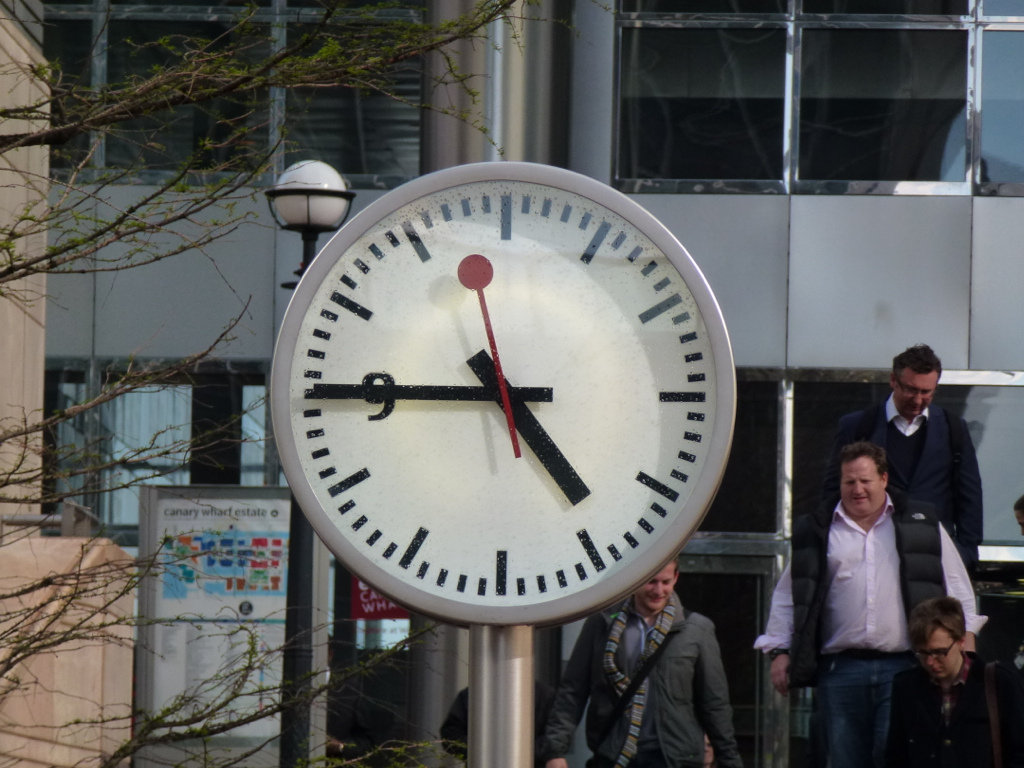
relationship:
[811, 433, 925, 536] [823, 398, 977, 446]
head above shoulders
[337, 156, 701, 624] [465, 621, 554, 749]
clock attached to pole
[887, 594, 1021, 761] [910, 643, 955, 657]
person wearing glasses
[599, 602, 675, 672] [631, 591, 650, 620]
scarf around neck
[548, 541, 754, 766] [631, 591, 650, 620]
man has neck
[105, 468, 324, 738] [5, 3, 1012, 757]
sign by building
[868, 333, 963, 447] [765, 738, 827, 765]
person walking on sidewalk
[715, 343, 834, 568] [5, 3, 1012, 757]
window on building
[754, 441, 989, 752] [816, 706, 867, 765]
man has leg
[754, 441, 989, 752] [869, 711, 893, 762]
man has leg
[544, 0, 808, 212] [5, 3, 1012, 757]
window on side of building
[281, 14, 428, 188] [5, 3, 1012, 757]
window on side of building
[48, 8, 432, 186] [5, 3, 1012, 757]
window on side of building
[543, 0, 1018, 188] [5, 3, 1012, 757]
window on side of building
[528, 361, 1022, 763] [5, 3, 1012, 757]
window on side of building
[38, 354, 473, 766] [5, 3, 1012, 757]
window on side of building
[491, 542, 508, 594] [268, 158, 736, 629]
6 position on clock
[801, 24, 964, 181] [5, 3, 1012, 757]
window on building